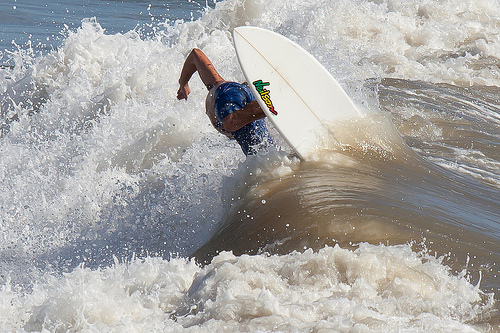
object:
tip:
[232, 25, 249, 42]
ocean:
[0, 0, 499, 332]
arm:
[178, 47, 225, 90]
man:
[177, 48, 275, 157]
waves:
[45, 65, 165, 231]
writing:
[251, 79, 279, 116]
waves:
[195, 76, 499, 328]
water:
[293, 192, 435, 303]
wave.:
[2, 2, 495, 330]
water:
[51, 127, 496, 265]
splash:
[332, 107, 395, 159]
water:
[0, 0, 499, 332]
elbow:
[185, 47, 205, 61]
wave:
[261, 193, 356, 244]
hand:
[177, 85, 193, 101]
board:
[230, 25, 365, 161]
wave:
[0, 0, 499, 332]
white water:
[0, 0, 499, 332]